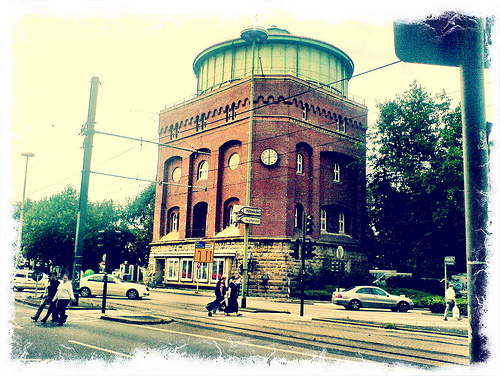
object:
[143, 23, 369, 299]
building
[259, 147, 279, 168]
clock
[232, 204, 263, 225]
street sign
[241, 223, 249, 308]
pole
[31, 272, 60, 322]
people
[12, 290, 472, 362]
street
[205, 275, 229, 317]
people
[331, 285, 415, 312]
car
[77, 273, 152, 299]
car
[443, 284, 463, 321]
man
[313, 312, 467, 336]
sidewalk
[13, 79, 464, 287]
trees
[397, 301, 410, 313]
front tire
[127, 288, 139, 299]
front tire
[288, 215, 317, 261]
trafic lights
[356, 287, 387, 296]
window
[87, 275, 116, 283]
window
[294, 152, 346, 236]
windows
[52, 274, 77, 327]
woman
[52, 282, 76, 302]
sweater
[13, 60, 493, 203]
wires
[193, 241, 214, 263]
sign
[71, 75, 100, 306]
telephone pole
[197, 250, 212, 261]
arrows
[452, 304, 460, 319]
bag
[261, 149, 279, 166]
face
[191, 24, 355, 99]
top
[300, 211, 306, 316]
pole